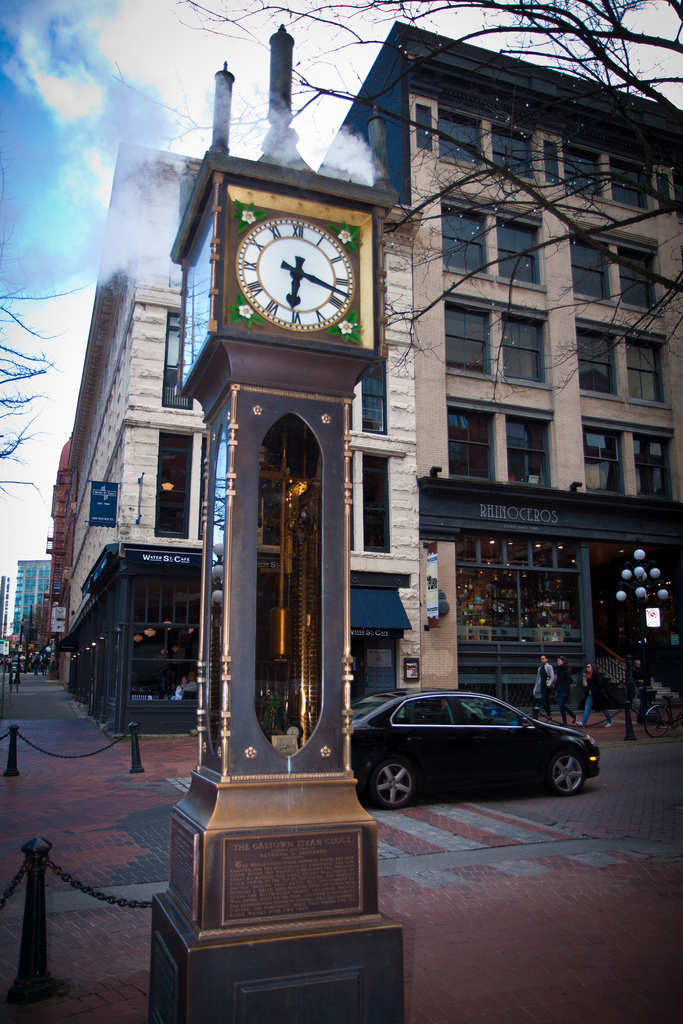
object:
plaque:
[219, 821, 368, 928]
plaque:
[172, 808, 200, 928]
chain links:
[14, 725, 134, 760]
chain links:
[47, 851, 156, 914]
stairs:
[596, 652, 642, 672]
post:
[8, 830, 59, 992]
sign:
[644, 607, 661, 629]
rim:
[552, 753, 586, 792]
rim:
[374, 759, 413, 806]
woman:
[571, 663, 615, 729]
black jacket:
[584, 670, 603, 697]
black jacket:
[556, 666, 568, 694]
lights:
[626, 544, 653, 566]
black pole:
[618, 607, 640, 742]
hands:
[281, 254, 349, 298]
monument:
[160, 158, 412, 1017]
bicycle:
[637, 688, 680, 738]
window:
[462, 690, 506, 725]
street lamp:
[613, 547, 669, 741]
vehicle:
[349, 677, 606, 811]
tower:
[142, 151, 410, 1022]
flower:
[233, 205, 265, 232]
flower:
[229, 291, 262, 335]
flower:
[336, 214, 365, 257]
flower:
[328, 310, 366, 345]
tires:
[549, 742, 589, 796]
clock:
[223, 211, 351, 331]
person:
[584, 655, 613, 727]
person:
[624, 655, 650, 718]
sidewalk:
[11, 662, 681, 761]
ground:
[30, 737, 661, 1017]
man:
[530, 640, 558, 723]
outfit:
[526, 663, 558, 724]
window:
[388, 693, 461, 728]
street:
[3, 736, 680, 901]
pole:
[642, 630, 663, 706]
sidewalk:
[7, 870, 639, 1020]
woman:
[549, 654, 577, 726]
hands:
[284, 254, 311, 315]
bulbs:
[609, 584, 633, 601]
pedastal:
[144, 378, 408, 1021]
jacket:
[532, 659, 555, 687]